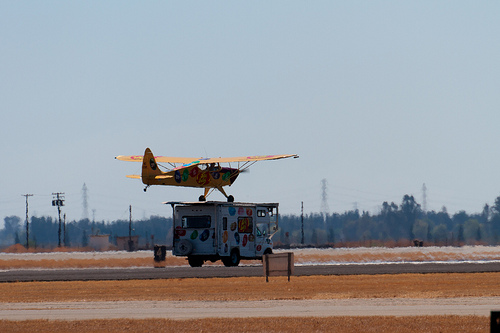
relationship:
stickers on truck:
[218, 222, 245, 257] [146, 191, 297, 278]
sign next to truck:
[263, 252, 294, 277] [172, 200, 278, 267]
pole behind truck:
[20, 191, 32, 247] [162, 197, 280, 270]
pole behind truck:
[51, 189, 63, 245] [162, 197, 280, 270]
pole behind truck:
[128, 203, 135, 238] [162, 197, 280, 270]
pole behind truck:
[298, 200, 307, 245] [162, 197, 280, 270]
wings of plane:
[110, 149, 300, 165] [113, 148, 300, 204]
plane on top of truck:
[127, 137, 307, 195] [172, 200, 278, 267]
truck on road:
[170, 203, 280, 265] [2, 263, 499, 280]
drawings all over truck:
[176, 207, 265, 251] [117, 115, 342, 298]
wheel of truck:
[214, 226, 278, 277] [96, 167, 336, 301]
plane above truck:
[113, 148, 300, 204] [164, 191, 286, 271]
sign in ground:
[263, 250, 295, 280] [0, 271, 496, 327]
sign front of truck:
[263, 252, 294, 277] [172, 200, 278, 267]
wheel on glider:
[228, 195, 233, 202] [104, 122, 294, 222]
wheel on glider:
[142, 187, 147, 192] [104, 122, 294, 222]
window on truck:
[184, 213, 214, 231] [172, 200, 278, 267]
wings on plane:
[206, 152, 301, 163] [110, 119, 304, 199]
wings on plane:
[117, 153, 305, 163] [114, 150, 305, 205]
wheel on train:
[222, 248, 241, 267] [132, 190, 299, 290]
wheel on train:
[173, 248, 220, 289] [132, 190, 299, 290]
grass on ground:
[1, 272, 500, 301] [0, 251, 498, 331]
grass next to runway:
[0, 320, 492, 329] [3, 265, 499, 275]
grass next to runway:
[1, 272, 500, 301] [3, 265, 499, 275]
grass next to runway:
[1, 257, 180, 265] [3, 265, 499, 275]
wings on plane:
[119, 133, 299, 180] [81, 115, 383, 265]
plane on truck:
[113, 148, 300, 204] [119, 174, 351, 304]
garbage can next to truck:
[146, 239, 168, 269] [165, 193, 275, 259]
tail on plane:
[123, 146, 175, 191] [108, 142, 304, 204]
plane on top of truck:
[113, 148, 300, 204] [170, 203, 280, 265]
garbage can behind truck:
[152, 244, 168, 270] [164, 191, 286, 271]